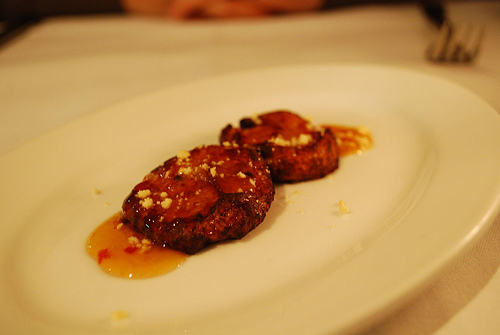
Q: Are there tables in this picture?
A: Yes, there is a table.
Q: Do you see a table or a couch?
A: Yes, there is a table.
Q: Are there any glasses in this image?
A: No, there are no glasses.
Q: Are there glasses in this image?
A: No, there are no glasses.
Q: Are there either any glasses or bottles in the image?
A: No, there are no glasses or bottles.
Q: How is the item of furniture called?
A: The piece of furniture is a table.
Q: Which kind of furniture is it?
A: The piece of furniture is a table.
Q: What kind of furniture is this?
A: This is a table.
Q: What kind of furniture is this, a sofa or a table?
A: This is a table.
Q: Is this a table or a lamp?
A: This is a table.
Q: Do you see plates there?
A: Yes, there is a plate.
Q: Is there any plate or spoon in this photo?
A: Yes, there is a plate.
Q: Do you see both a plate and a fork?
A: Yes, there are both a plate and a fork.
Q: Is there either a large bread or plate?
A: Yes, there is a large plate.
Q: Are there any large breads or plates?
A: Yes, there is a large plate.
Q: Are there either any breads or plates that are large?
A: Yes, the plate is large.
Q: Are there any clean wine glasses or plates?
A: Yes, there is a clean plate.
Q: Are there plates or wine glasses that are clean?
A: Yes, the plate is clean.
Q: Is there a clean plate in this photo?
A: Yes, there is a clean plate.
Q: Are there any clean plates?
A: Yes, there is a clean plate.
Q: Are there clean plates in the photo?
A: Yes, there is a clean plate.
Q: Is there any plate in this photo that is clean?
A: Yes, there is a plate that is clean.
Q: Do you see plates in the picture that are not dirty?
A: Yes, there is a clean plate.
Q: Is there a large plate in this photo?
A: Yes, there is a large plate.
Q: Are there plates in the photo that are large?
A: Yes, there is a plate that is large.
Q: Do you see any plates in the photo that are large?
A: Yes, there is a plate that is large.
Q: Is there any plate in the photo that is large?
A: Yes, there is a plate that is large.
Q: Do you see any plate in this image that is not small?
A: Yes, there is a large plate.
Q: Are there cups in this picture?
A: No, there are no cups.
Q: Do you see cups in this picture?
A: No, there are no cups.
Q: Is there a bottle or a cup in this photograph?
A: No, there are no cups or bottles.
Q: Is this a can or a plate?
A: This is a plate.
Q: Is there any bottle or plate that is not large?
A: No, there is a plate but it is large.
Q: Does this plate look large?
A: Yes, the plate is large.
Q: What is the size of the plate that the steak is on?
A: The plate is large.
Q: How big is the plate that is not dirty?
A: The plate is large.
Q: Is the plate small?
A: No, the plate is large.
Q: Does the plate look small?
A: No, the plate is large.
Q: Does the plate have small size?
A: No, the plate is large.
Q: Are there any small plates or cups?
A: No, there is a plate but it is large.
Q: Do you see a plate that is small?
A: No, there is a plate but it is large.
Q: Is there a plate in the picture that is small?
A: No, there is a plate but it is large.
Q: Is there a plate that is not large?
A: No, there is a plate but it is large.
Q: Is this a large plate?
A: Yes, this is a large plate.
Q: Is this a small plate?
A: No, this is a large plate.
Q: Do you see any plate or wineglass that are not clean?
A: No, there is a plate but it is clean.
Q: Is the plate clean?
A: Yes, the plate is clean.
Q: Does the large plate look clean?
A: Yes, the plate is clean.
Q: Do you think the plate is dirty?
A: No, the plate is clean.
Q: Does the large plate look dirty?
A: No, the plate is clean.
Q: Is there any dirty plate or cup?
A: No, there is a plate but it is clean.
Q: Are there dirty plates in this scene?
A: No, there is a plate but it is clean.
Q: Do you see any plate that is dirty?
A: No, there is a plate but it is clean.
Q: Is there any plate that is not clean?
A: No, there is a plate but it is clean.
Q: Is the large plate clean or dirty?
A: The plate is clean.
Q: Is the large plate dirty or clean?
A: The plate is clean.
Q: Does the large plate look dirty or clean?
A: The plate is clean.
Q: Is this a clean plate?
A: Yes, this is a clean plate.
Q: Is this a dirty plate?
A: No, this is a clean plate.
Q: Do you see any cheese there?
A: Yes, there is cheese.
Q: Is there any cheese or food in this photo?
A: Yes, there is cheese.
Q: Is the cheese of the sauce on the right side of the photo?
A: Yes, the cheese is on the right of the image.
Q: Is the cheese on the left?
A: No, the cheese is on the right of the image.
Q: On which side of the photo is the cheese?
A: The cheese is on the right of the image.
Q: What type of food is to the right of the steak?
A: The food is cheese.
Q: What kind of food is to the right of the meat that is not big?
A: The food is cheese.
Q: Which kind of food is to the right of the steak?
A: The food is cheese.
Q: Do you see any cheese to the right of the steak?
A: Yes, there is cheese to the right of the steak.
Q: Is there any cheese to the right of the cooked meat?
A: Yes, there is cheese to the right of the steak.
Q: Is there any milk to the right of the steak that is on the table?
A: No, there is cheese to the right of the steak.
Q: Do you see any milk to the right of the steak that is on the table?
A: No, there is cheese to the right of the steak.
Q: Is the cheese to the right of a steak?
A: Yes, the cheese is to the right of a steak.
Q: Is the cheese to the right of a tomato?
A: No, the cheese is to the right of a steak.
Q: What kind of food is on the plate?
A: The food is cheese.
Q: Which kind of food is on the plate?
A: The food is cheese.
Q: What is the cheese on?
A: The cheese is on the plate.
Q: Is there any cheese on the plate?
A: Yes, there is cheese on the plate.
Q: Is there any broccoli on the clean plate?
A: No, there is cheese on the plate.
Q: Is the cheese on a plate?
A: Yes, the cheese is on a plate.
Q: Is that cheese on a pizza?
A: No, the cheese is on a plate.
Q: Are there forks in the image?
A: Yes, there is a fork.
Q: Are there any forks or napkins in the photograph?
A: Yes, there is a fork.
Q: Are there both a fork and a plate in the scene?
A: Yes, there are both a fork and a plate.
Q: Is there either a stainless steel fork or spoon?
A: Yes, there is a stainless steel fork.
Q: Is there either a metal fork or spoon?
A: Yes, there is a metal fork.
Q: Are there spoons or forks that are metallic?
A: Yes, the fork is metallic.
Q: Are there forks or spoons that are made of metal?
A: Yes, the fork is made of metal.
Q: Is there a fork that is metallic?
A: Yes, there is a metal fork.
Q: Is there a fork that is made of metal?
A: Yes, there is a fork that is made of metal.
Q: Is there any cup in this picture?
A: No, there are no cups.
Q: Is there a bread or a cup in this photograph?
A: No, there are no cups or breads.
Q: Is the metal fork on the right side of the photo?
A: Yes, the fork is on the right of the image.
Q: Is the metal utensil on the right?
A: Yes, the fork is on the right of the image.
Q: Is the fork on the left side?
A: No, the fork is on the right of the image.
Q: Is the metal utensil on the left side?
A: No, the fork is on the right of the image.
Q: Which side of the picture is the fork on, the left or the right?
A: The fork is on the right of the image.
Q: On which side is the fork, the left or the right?
A: The fork is on the right of the image.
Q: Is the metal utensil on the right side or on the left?
A: The fork is on the right of the image.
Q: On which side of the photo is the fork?
A: The fork is on the right of the image.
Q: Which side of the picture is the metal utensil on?
A: The fork is on the right of the image.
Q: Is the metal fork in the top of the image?
A: Yes, the fork is in the top of the image.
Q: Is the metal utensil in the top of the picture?
A: Yes, the fork is in the top of the image.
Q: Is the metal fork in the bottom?
A: No, the fork is in the top of the image.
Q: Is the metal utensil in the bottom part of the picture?
A: No, the fork is in the top of the image.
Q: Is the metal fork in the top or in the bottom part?
A: The fork is in the top of the image.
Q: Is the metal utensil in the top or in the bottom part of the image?
A: The fork is in the top of the image.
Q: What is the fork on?
A: The fork is on the table.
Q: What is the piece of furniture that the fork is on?
A: The piece of furniture is a table.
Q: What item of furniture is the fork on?
A: The fork is on the table.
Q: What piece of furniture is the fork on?
A: The fork is on the table.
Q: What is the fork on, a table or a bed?
A: The fork is on a table.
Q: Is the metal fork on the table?
A: Yes, the fork is on the table.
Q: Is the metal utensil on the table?
A: Yes, the fork is on the table.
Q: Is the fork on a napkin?
A: No, the fork is on the table.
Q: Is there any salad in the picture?
A: No, there is no salad.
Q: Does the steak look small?
A: Yes, the steak is small.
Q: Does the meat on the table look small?
A: Yes, the steak is small.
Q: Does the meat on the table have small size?
A: Yes, the steak is small.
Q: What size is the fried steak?
A: The steak is small.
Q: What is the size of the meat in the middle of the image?
A: The steak is small.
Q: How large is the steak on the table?
A: The steak is small.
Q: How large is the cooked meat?
A: The steak is small.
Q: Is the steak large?
A: No, the steak is small.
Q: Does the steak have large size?
A: No, the steak is small.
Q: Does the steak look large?
A: No, the steak is small.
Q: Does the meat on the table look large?
A: No, the steak is small.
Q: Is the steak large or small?
A: The steak is small.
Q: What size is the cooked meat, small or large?
A: The steak is small.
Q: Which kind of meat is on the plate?
A: The meat is a steak.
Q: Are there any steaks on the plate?
A: Yes, there is a steak on the plate.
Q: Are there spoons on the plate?
A: No, there is a steak on the plate.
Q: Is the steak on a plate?
A: Yes, the steak is on a plate.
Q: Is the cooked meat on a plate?
A: Yes, the steak is on a plate.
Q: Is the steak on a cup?
A: No, the steak is on a plate.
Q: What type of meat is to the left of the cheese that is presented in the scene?
A: The meat is a steak.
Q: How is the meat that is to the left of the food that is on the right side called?
A: The meat is a steak.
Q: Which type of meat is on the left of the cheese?
A: The meat is a steak.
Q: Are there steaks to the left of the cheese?
A: Yes, there is a steak to the left of the cheese.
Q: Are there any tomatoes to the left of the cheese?
A: No, there is a steak to the left of the cheese.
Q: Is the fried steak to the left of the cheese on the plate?
A: Yes, the steak is to the left of the cheese.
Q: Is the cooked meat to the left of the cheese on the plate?
A: Yes, the steak is to the left of the cheese.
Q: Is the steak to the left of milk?
A: No, the steak is to the left of the cheese.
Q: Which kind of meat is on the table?
A: The meat is a steak.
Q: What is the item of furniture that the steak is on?
A: The piece of furniture is a table.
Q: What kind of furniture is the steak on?
A: The steak is on the table.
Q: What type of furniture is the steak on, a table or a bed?
A: The steak is on a table.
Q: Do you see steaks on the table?
A: Yes, there is a steak on the table.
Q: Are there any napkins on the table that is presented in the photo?
A: No, there is a steak on the table.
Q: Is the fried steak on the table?
A: Yes, the steak is on the table.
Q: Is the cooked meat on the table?
A: Yes, the steak is on the table.